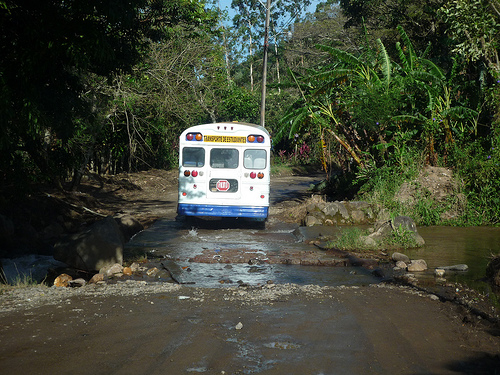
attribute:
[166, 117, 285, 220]
bus — lit, white, blue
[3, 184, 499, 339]
water — brown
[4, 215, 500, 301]
stones — gray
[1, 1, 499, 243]
trees — thick, green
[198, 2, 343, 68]
sky — blue